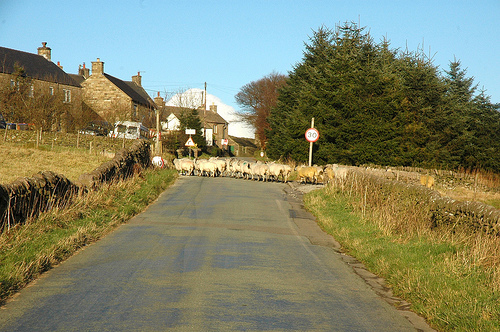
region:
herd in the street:
[170, 149, 371, 187]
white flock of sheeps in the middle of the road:
[171, 152, 321, 184]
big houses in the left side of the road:
[1, 37, 231, 152]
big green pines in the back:
[262, 26, 497, 177]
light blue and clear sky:
[1, 4, 498, 102]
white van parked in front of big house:
[108, 115, 148, 140]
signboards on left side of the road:
[151, 131, 229, 168]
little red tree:
[236, 72, 284, 154]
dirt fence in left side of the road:
[1, 137, 154, 225]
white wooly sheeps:
[170, 153, 292, 183]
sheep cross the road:
[152, 150, 337, 185]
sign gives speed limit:
[302, 116, 319, 163]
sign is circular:
[304, 125, 318, 142]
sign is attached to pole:
[304, 127, 319, 142]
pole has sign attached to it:
[307, 115, 315, 165]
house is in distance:
[80, 57, 153, 127]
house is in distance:
[150, 91, 229, 146]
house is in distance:
[0, 42, 85, 132]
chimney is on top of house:
[132, 70, 142, 87]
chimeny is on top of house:
[37, 40, 52, 60]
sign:
[301, 122, 329, 152]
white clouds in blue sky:
[74, 6, 112, 37]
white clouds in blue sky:
[197, 11, 239, 38]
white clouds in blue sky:
[434, 1, 495, 36]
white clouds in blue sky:
[378, 13, 420, 30]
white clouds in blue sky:
[232, 8, 296, 39]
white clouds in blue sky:
[250, 26, 294, 58]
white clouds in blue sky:
[181, 22, 233, 63]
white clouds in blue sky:
[112, 25, 172, 60]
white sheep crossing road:
[195, 153, 269, 187]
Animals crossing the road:
[171, 154, 293, 182]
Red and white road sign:
[303, 114, 320, 166]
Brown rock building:
[81, 57, 160, 135]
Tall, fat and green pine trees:
[260, 10, 497, 175]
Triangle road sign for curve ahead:
[180, 132, 195, 152]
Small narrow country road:
[0, 155, 432, 325]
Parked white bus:
[110, 116, 150, 136]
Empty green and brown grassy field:
[431, 168, 497, 202]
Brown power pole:
[202, 80, 208, 107]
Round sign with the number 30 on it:
[304, 127, 320, 142]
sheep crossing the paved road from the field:
[158, 142, 300, 195]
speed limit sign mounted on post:
[302, 111, 325, 158]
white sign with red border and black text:
[302, 127, 328, 150]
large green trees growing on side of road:
[275, 30, 478, 175]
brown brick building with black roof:
[70, 57, 153, 140]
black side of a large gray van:
[107, 115, 151, 151]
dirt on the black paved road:
[178, 200, 283, 253]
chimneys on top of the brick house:
[81, 57, 116, 74]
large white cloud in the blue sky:
[172, 76, 244, 126]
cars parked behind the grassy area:
[65, 106, 170, 149]